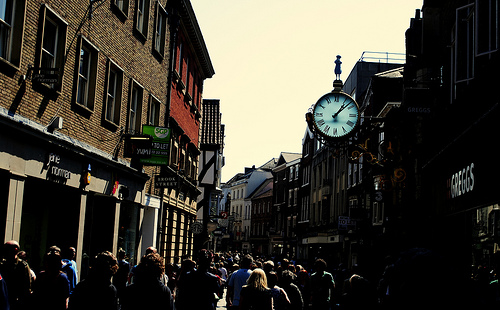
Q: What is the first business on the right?
A: Greggs.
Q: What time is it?
A: 1:07.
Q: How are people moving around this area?
A: Walking.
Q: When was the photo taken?
A: Early afternoon.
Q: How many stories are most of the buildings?
A: 3.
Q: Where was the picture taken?
A: In a city.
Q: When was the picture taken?
A: Daytime.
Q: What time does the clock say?
A: 1:08.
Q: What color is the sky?
A: White.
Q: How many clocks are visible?
A: One.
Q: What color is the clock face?
A: White.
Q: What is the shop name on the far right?
A: GREGGS.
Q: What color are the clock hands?
A: Black.